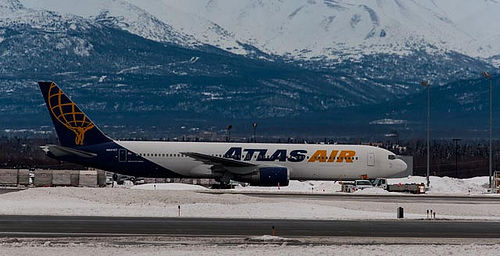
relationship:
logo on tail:
[47, 81, 94, 146] [39, 81, 118, 143]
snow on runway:
[119, 182, 308, 216] [1, 187, 499, 254]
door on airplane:
[363, 147, 377, 168] [13, 77, 406, 191]